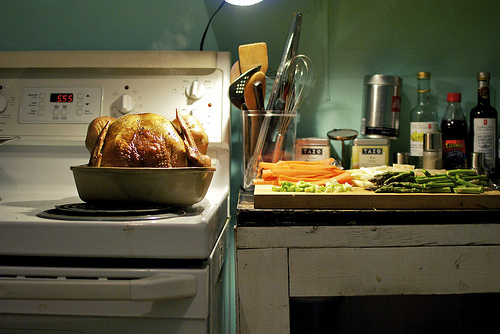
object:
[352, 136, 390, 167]
tea tin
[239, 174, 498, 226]
counter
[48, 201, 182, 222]
grill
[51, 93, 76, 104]
lights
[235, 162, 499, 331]
table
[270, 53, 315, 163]
kitchen utensil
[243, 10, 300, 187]
kitchen utensil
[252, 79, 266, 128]
kitchen utensil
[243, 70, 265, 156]
kitchen utensil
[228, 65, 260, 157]
kitchen utensil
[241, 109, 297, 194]
clear container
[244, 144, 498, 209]
chopping board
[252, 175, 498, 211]
board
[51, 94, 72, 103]
time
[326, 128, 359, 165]
container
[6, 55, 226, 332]
stove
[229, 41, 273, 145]
utensil h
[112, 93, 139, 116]
dial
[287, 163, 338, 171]
carrots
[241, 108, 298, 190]
bucket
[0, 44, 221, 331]
oven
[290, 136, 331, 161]
container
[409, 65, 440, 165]
glass bottle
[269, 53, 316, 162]
whisk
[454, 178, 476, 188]
veggies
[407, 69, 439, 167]
bottle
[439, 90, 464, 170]
bottle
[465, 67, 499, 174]
bottle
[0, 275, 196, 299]
handle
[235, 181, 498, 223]
counter top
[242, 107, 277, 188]
kitchen utensils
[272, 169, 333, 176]
carrots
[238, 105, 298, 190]
utensil holder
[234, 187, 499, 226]
top